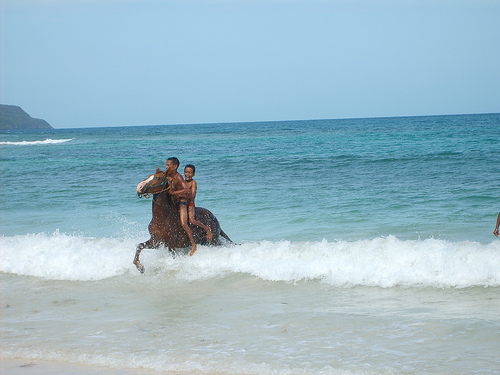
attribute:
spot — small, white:
[141, 174, 157, 184]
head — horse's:
[133, 165, 174, 201]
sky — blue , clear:
[0, 2, 498, 134]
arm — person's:
[484, 205, 499, 239]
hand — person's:
[487, 223, 499, 243]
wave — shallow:
[269, 222, 481, 303]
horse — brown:
[131, 166, 238, 278]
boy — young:
[181, 165, 213, 240]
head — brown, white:
[126, 163, 156, 203]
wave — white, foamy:
[1, 227, 498, 300]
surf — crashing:
[0, 225, 499, 292]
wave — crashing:
[9, 99, 497, 370]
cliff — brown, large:
[1, 105, 56, 136]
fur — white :
[124, 174, 158, 189]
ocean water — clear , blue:
[5, 122, 497, 372]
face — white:
[137, 168, 166, 198]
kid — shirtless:
[176, 165, 215, 246]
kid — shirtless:
[156, 152, 198, 256]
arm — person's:
[492, 213, 499, 238]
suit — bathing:
[186, 197, 198, 212]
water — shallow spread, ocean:
[5, 105, 498, 366]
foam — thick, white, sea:
[4, 230, 497, 290]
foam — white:
[282, 232, 460, 294]